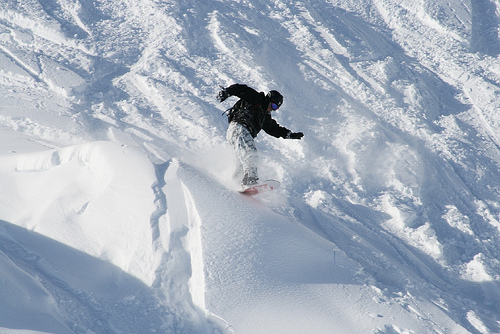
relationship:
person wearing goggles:
[212, 81, 305, 197] [274, 95, 285, 109]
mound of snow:
[10, 135, 320, 316] [1, 1, 500, 330]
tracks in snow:
[0, 19, 229, 140] [1, 1, 500, 330]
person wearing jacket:
[212, 81, 305, 197] [214, 83, 295, 140]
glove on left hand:
[289, 131, 304, 140] [287, 128, 306, 140]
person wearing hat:
[212, 81, 305, 197] [262, 89, 286, 111]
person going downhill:
[212, 81, 305, 197] [226, 147, 499, 333]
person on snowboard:
[212, 81, 305, 197] [237, 177, 279, 201]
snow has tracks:
[1, 1, 500, 330] [0, 19, 229, 140]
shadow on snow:
[2, 211, 183, 332] [1, 1, 500, 330]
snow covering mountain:
[1, 1, 500, 330] [1, 2, 500, 332]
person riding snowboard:
[212, 81, 305, 197] [237, 177, 279, 201]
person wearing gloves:
[212, 81, 305, 197] [216, 86, 307, 140]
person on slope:
[212, 81, 305, 197] [7, 79, 498, 316]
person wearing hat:
[212, 81, 305, 197] [267, 89, 284, 111]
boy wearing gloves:
[211, 83, 305, 188] [216, 86, 307, 140]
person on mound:
[212, 81, 305, 197] [10, 135, 320, 316]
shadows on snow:
[2, 210, 491, 332] [1, 1, 500, 330]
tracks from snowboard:
[0, 19, 229, 140] [237, 177, 279, 201]